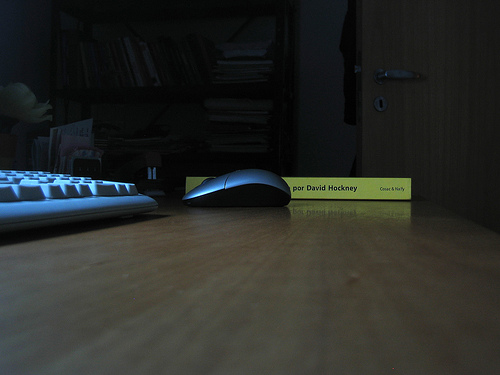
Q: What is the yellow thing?
A: Directory.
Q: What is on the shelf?
A: Books and documents.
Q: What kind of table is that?
A: Brown.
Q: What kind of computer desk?
A: Laminated wood pattern.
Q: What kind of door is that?
A: Wooden door with handle and keyhole.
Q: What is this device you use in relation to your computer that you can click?
A: Mouse.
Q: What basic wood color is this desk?
A: Brown.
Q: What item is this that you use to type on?
A: Keyboard.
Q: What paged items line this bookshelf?
A: Books.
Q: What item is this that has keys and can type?
A: Keyboard.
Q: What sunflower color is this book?
A: Yellow.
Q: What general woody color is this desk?
A: Brown.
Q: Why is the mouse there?
A: To use.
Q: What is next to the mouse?
A: Keyboard.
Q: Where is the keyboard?
A: Next to the mouse.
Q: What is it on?
A: Desk.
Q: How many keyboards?
A: 1.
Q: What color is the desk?
A: Brown.